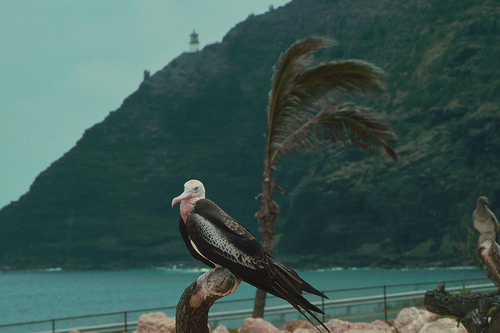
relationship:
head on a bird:
[168, 177, 208, 219] [167, 173, 336, 331]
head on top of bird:
[168, 177, 208, 219] [139, 176, 343, 328]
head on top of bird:
[168, 177, 208, 219] [128, 171, 299, 298]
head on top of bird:
[168, 177, 208, 219] [96, 135, 351, 326]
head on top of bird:
[168, 177, 208, 219] [167, 173, 336, 331]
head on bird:
[168, 177, 208, 219] [167, 173, 336, 331]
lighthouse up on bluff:
[167, 21, 214, 66] [149, 41, 231, 96]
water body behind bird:
[0, 269, 494, 331] [165, 175, 307, 295]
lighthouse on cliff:
[167, 21, 214, 66] [155, 41, 226, 104]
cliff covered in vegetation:
[26, 11, 497, 236] [0, 7, 498, 267]